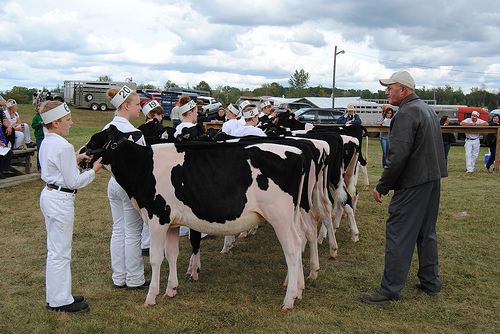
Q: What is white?
A: Uniform.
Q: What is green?
A: Grass.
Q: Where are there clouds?
A: Wind.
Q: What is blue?
A: Sky.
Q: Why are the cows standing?
A: Being judged.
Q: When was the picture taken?
A: Daytime.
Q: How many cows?
A: Five.